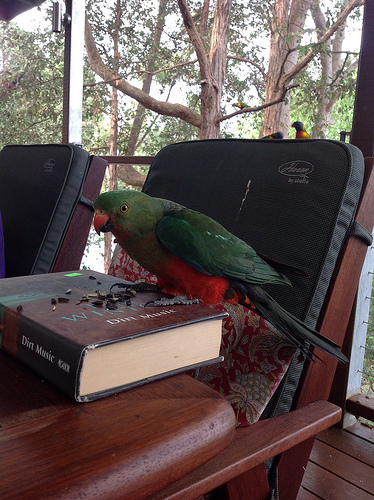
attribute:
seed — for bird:
[49, 272, 131, 308]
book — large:
[1, 268, 227, 404]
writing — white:
[21, 334, 75, 372]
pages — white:
[81, 316, 222, 402]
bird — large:
[94, 192, 348, 366]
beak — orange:
[93, 211, 109, 236]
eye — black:
[120, 204, 128, 209]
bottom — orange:
[157, 255, 250, 305]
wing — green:
[155, 208, 291, 286]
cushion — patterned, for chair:
[107, 245, 296, 425]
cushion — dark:
[137, 139, 366, 410]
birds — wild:
[260, 117, 311, 139]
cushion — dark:
[2, 142, 91, 279]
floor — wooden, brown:
[300, 422, 372, 499]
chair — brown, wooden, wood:
[134, 135, 371, 496]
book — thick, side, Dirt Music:
[0, 266, 251, 402]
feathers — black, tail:
[247, 272, 361, 374]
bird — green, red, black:
[88, 184, 357, 369]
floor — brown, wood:
[291, 413, 371, 497]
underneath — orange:
[116, 233, 251, 316]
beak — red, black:
[87, 203, 121, 238]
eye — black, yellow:
[115, 194, 129, 216]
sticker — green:
[60, 266, 87, 282]